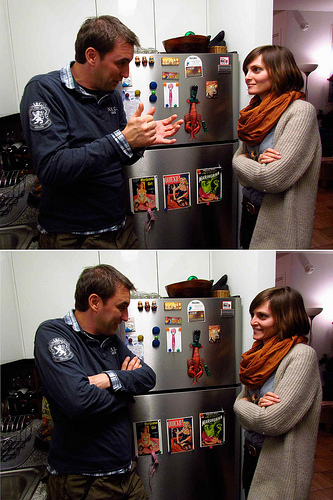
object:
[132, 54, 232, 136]
magnets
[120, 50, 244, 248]
fridge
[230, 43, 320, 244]
woman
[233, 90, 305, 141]
scarf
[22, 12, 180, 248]
man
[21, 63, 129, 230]
shirt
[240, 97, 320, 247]
cardigan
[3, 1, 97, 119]
cabinets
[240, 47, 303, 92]
hair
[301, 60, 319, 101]
light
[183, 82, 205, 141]
lobster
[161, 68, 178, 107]
picture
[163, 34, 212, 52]
basket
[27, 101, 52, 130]
patch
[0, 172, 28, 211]
strainer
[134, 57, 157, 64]
magnets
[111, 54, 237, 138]
door